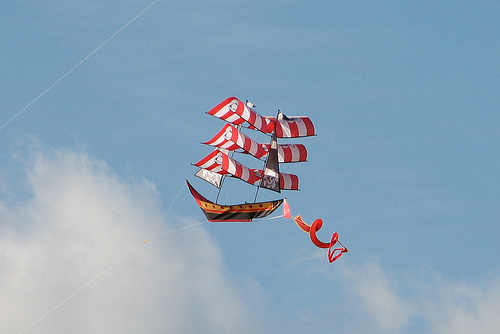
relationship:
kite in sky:
[187, 96, 351, 264] [2, 1, 500, 334]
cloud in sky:
[0, 159, 232, 332] [2, 1, 500, 334]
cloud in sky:
[351, 271, 498, 334] [2, 1, 500, 334]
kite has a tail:
[187, 96, 351, 264] [282, 200, 348, 263]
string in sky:
[15, 185, 200, 333] [2, 1, 500, 334]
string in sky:
[2, 2, 156, 132] [2, 1, 500, 334]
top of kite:
[204, 97, 319, 137] [187, 96, 351, 264]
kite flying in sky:
[187, 96, 351, 264] [2, 1, 500, 334]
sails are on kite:
[195, 96, 316, 192] [187, 96, 351, 264]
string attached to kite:
[15, 185, 200, 333] [187, 96, 351, 264]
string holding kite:
[15, 185, 200, 333] [187, 96, 351, 264]